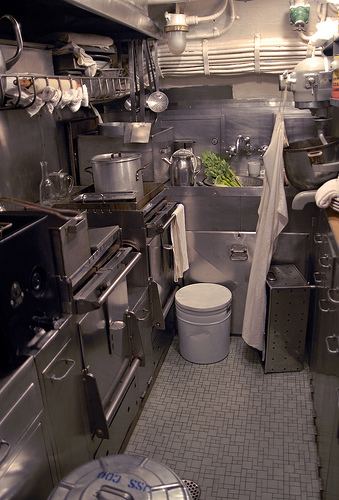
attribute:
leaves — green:
[198, 149, 239, 186]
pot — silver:
[94, 152, 143, 194]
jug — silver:
[165, 151, 198, 186]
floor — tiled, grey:
[206, 382, 286, 467]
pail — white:
[175, 283, 233, 365]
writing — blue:
[95, 471, 150, 493]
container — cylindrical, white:
[171, 284, 234, 362]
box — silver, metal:
[269, 271, 302, 374]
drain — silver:
[185, 477, 204, 497]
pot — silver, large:
[93, 152, 144, 206]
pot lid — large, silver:
[95, 154, 138, 165]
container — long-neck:
[36, 163, 56, 201]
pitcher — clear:
[55, 173, 77, 201]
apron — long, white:
[264, 134, 288, 235]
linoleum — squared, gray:
[182, 392, 283, 456]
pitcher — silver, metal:
[164, 149, 198, 187]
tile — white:
[203, 457, 211, 465]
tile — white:
[184, 449, 193, 457]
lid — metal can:
[48, 458, 183, 498]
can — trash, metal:
[42, 450, 200, 498]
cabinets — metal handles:
[135, 200, 188, 241]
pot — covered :
[90, 149, 150, 199]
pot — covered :
[83, 144, 145, 200]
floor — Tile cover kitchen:
[157, 366, 303, 494]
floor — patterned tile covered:
[142, 377, 304, 479]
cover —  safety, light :
[173, 277, 235, 307]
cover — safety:
[285, 7, 326, 39]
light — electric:
[288, 18, 327, 56]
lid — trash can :
[45, 456, 178, 496]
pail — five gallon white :
[169, 277, 237, 368]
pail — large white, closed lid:
[166, 270, 231, 362]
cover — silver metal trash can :
[52, 451, 227, 498]